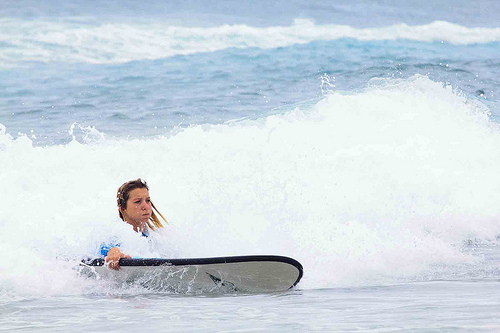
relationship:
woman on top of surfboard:
[84, 177, 189, 264] [81, 255, 304, 296]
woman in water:
[110, 177, 167, 264] [0, 1, 498, 329]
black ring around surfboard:
[167, 252, 245, 279] [163, 255, 275, 293]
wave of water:
[0, 67, 500, 275] [25, 122, 421, 329]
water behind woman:
[25, 122, 421, 329] [86, 166, 191, 266]